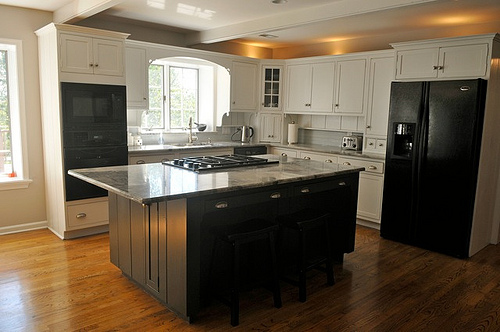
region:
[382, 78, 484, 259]
a tall black refrigerator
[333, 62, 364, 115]
a white cabinet door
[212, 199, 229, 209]
a silver cabinet handle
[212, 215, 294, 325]
a dark stool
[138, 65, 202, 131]
a kitchen window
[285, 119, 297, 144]
a roll of paper towels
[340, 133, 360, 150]
a gray toaster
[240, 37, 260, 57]
a bright orange light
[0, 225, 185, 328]
light brown hardwood floor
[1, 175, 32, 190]
part of a white windowsill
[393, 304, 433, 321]
The floor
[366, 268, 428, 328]
The floor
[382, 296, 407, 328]
The floor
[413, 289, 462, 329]
The floor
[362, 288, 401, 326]
The floor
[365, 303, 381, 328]
The floor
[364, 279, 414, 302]
The floor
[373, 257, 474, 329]
The floor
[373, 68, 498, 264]
The kitchen has a black refrigerator.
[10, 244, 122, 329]
The flooring is wood.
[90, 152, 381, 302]
The island sits in the middle of the kitchen.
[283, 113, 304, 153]
Paper towel roll on the counter.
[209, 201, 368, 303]
Black stools at the island.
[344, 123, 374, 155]
A toaster sits in the counter top.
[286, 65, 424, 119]
The cabinets are white.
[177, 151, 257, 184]
The stove burner is on the island.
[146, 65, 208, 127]
A window in the kitchen above the sink.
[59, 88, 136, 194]
An oven under the built in microwave.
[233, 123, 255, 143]
Coffee maker on counter.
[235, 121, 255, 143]
Stainless steel coffee maker.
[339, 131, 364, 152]
a toaster on the counter.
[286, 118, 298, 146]
A roll of paper towels.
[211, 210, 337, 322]
Two black stools.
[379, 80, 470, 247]
A fridge thats black.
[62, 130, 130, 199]
A large oven in the wall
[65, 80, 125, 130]
A black microwave in the wall.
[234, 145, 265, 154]
The top of a dishwasher.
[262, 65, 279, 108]
A cupboard with dishes.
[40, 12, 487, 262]
The kitchen has white cabinets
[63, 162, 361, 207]
The counter top is grey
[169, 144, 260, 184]
The stove is black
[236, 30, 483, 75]
Lights above the cabinets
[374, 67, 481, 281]
The fridge is black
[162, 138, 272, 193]
The stove is in the island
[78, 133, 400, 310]
Island in the middle of the kitchen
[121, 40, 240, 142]
Large window above the sink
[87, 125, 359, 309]
The island has black cabinets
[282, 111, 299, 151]
White toilet paper roll on counter